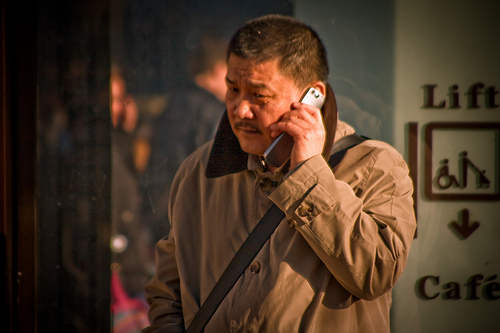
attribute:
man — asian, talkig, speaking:
[146, 15, 420, 331]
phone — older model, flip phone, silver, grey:
[265, 86, 326, 169]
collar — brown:
[203, 110, 247, 180]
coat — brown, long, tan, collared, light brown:
[144, 84, 417, 332]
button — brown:
[249, 259, 261, 275]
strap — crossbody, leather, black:
[189, 132, 363, 330]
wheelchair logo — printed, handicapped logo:
[436, 155, 459, 191]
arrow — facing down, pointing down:
[447, 210, 483, 241]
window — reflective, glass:
[37, 2, 393, 332]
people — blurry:
[110, 37, 227, 332]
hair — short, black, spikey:
[224, 13, 328, 89]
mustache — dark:
[231, 122, 261, 133]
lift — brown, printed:
[420, 80, 498, 112]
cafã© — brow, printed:
[417, 271, 499, 303]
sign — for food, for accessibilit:
[390, 1, 499, 332]